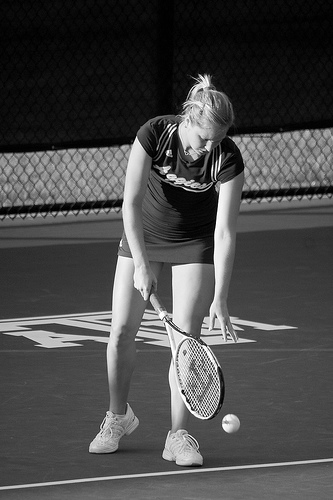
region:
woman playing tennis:
[88, 75, 242, 466]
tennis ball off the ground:
[222, 415, 240, 435]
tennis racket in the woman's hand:
[150, 290, 222, 421]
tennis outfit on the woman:
[116, 112, 244, 266]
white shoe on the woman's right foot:
[89, 405, 137, 459]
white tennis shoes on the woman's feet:
[88, 400, 203, 464]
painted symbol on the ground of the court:
[0, 308, 296, 347]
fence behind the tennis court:
[1, 0, 328, 224]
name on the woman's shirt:
[152, 162, 212, 194]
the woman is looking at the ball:
[89, 74, 245, 466]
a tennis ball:
[222, 412, 243, 436]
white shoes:
[90, 421, 121, 452]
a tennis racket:
[172, 329, 227, 417]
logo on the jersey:
[150, 163, 209, 199]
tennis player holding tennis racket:
[130, 267, 162, 303]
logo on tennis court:
[6, 311, 100, 350]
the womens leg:
[110, 290, 136, 391]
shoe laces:
[183, 429, 197, 448]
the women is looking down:
[183, 108, 233, 153]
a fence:
[4, 26, 131, 161]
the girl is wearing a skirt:
[114, 216, 220, 272]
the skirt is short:
[113, 214, 218, 270]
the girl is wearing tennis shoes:
[81, 396, 210, 472]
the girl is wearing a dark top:
[120, 102, 247, 251]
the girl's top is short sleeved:
[127, 111, 249, 242]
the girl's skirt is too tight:
[115, 217, 223, 273]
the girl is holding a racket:
[140, 280, 228, 430]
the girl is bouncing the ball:
[215, 407, 243, 439]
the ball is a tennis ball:
[218, 409, 242, 441]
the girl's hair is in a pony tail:
[178, 68, 236, 131]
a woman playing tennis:
[112, 70, 270, 481]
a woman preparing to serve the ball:
[132, 82, 256, 484]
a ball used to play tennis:
[215, 408, 245, 441]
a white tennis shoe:
[159, 423, 211, 472]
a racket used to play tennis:
[145, 286, 226, 428]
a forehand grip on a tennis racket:
[128, 258, 160, 312]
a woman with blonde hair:
[179, 73, 240, 168]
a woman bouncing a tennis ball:
[128, 59, 265, 477]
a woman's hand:
[199, 296, 242, 344]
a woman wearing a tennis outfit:
[124, 68, 260, 277]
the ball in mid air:
[221, 413, 240, 433]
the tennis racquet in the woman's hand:
[142, 277, 223, 420]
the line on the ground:
[4, 446, 331, 491]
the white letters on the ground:
[6, 287, 302, 351]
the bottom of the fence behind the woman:
[1, 126, 332, 223]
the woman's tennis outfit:
[116, 114, 244, 264]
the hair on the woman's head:
[179, 72, 232, 130]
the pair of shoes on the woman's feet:
[88, 402, 202, 466]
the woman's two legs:
[89, 246, 205, 465]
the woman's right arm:
[122, 120, 159, 298]